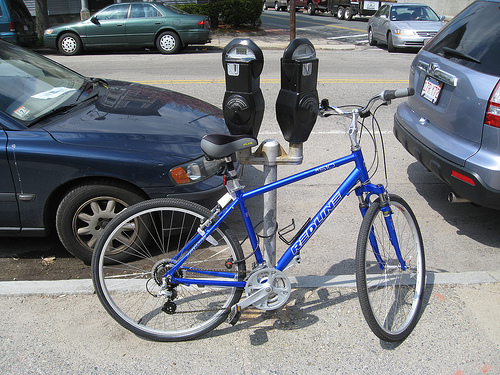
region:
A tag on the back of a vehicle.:
[421, 75, 443, 102]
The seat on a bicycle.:
[198, 130, 258, 160]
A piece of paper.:
[27, 82, 77, 101]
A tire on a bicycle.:
[89, 195, 248, 343]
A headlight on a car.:
[396, 25, 417, 40]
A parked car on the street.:
[38, 0, 214, 52]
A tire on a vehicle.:
[51, 179, 159, 267]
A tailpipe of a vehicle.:
[441, 188, 473, 206]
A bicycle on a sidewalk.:
[88, 85, 425, 345]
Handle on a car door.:
[111, 19, 123, 27]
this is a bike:
[124, 80, 374, 370]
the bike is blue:
[206, 177, 293, 298]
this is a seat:
[189, 116, 216, 151]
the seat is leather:
[194, 147, 263, 186]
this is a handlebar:
[325, 110, 426, 164]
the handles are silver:
[305, 48, 455, 343]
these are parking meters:
[126, 51, 296, 145]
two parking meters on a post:
[203, 36, 323, 311]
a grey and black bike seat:
[196, 117, 256, 166]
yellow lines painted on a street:
[312, 64, 407, 104]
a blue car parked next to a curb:
[2, 58, 212, 315]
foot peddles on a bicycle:
[215, 266, 293, 343]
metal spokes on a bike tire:
[105, 202, 223, 349]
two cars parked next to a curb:
[112, 26, 479, 283]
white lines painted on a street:
[335, 21, 368, 66]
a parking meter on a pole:
[214, 29, 280, 276]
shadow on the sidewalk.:
[289, 319, 318, 334]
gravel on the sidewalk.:
[22, 345, 52, 363]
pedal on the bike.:
[212, 309, 255, 326]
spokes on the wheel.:
[130, 236, 142, 277]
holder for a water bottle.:
[276, 216, 305, 244]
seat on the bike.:
[201, 139, 255, 156]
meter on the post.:
[285, 43, 315, 108]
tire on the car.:
[159, 31, 176, 48]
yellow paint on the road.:
[350, 73, 377, 88]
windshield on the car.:
[14, 64, 51, 97]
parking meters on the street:
[216, 30, 323, 164]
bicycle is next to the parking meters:
[93, 25, 432, 372]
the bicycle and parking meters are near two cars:
[1, 36, 499, 371]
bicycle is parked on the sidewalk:
[89, 113, 436, 349]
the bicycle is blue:
[93, 127, 442, 346]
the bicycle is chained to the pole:
[88, 110, 448, 352]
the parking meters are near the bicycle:
[89, 35, 429, 352]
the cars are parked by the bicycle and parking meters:
[0, 37, 496, 342]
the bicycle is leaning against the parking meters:
[88, 37, 438, 351]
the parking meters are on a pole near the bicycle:
[91, 27, 432, 354]